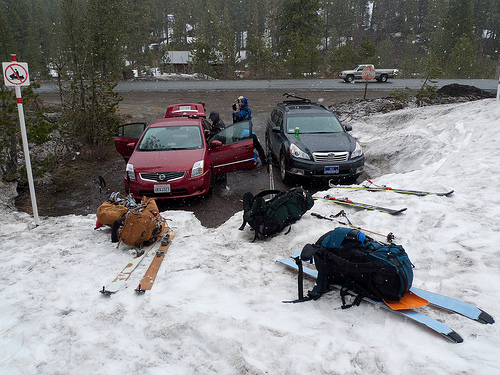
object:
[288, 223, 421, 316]
bag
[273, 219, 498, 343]
skis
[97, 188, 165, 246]
bag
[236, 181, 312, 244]
bag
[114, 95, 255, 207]
vehicle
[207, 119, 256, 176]
door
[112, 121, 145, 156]
door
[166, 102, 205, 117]
trunk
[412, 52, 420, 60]
snow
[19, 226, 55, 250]
ground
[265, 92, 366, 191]
vehicle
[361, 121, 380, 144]
snow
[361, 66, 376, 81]
sign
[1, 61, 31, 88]
sign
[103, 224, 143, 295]
skis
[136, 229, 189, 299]
skis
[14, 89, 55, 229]
pole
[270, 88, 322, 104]
rack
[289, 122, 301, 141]
bottle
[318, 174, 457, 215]
skis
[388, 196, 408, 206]
snow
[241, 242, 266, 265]
snow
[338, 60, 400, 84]
car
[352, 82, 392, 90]
road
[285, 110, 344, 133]
windshield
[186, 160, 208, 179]
headlight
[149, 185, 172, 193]
plate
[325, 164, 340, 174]
plate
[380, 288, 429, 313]
shovel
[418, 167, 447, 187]
snow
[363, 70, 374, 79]
stop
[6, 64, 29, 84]
picture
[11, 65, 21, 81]
line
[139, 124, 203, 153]
windshield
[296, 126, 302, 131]
top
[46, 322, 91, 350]
snow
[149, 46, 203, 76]
cabin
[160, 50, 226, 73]
picture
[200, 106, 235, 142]
people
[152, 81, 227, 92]
street